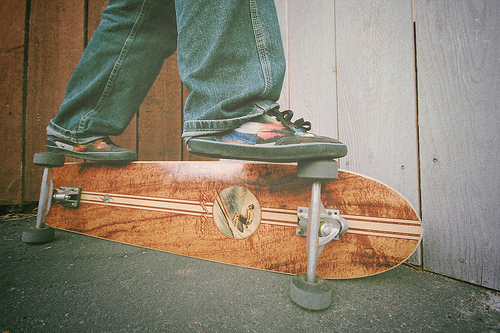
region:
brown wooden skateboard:
[18, 147, 424, 312]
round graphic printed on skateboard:
[213, 186, 263, 237]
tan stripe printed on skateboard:
[81, 191, 215, 217]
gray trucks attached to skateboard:
[296, 180, 347, 282]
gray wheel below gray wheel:
[289, 274, 332, 311]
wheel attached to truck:
[297, 158, 339, 180]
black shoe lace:
[271, 104, 312, 131]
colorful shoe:
[188, 107, 348, 163]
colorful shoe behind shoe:
[46, 129, 137, 160]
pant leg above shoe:
[176, 0, 288, 136]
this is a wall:
[390, 60, 495, 155]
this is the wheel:
[289, 272, 352, 313]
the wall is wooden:
[390, 45, 465, 125]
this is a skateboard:
[155, 155, 365, 300]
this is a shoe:
[250, 130, 305, 150]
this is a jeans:
[170, 30, 255, 90]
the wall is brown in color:
[10, 15, 60, 75]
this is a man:
[230, 200, 255, 230]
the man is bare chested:
[240, 206, 250, 221]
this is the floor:
[107, 261, 162, 298]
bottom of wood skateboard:
[26, 149, 426, 285]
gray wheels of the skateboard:
[15, 147, 340, 312]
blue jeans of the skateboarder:
[38, 4, 295, 142]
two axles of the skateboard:
[23, 174, 328, 271]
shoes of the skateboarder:
[42, 119, 344, 163]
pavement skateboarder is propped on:
[8, 218, 484, 331]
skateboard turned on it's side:
[20, 135, 430, 310]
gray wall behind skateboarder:
[224, 4, 499, 296]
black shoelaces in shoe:
[269, 107, 320, 132]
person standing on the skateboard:
[22, 6, 342, 165]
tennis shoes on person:
[199, 117, 380, 161]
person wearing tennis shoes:
[198, 105, 351, 184]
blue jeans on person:
[175, 15, 317, 126]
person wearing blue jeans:
[168, 60, 303, 151]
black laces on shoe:
[272, 97, 335, 146]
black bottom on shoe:
[272, 127, 369, 158]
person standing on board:
[189, 104, 382, 231]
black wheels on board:
[306, 159, 341, 330]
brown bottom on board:
[157, 154, 325, 257]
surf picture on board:
[219, 187, 281, 253]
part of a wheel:
[296, 271, 325, 304]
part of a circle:
[203, 176, 250, 241]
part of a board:
[182, 224, 209, 251]